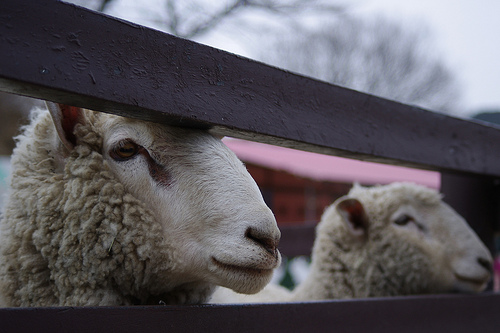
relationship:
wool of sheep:
[0, 105, 210, 309] [0, 98, 284, 307]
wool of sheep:
[287, 174, 442, 298] [293, 181, 494, 303]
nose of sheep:
[244, 218, 286, 253] [0, 98, 284, 307]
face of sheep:
[94, 109, 281, 292] [0, 98, 284, 307]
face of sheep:
[389, 197, 494, 288] [303, 183, 495, 293]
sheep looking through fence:
[12, 49, 288, 331] [2, 0, 499, 332]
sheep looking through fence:
[293, 181, 494, 303] [2, 0, 499, 332]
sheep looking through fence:
[0, 98, 284, 307] [2, 0, 499, 332]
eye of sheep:
[101, 128, 149, 164] [0, 98, 284, 307]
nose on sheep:
[244, 209, 286, 253] [0, 98, 284, 307]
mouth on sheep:
[208, 250, 283, 285] [0, 98, 284, 307]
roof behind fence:
[210, 120, 460, 205] [2, 0, 499, 332]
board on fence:
[4, 292, 495, 330] [2, 0, 499, 332]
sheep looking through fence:
[0, 98, 284, 307] [176, 42, 453, 162]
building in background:
[233, 141, 443, 197] [0, 8, 497, 213]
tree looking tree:
[226, 2, 464, 114] [68, 1, 347, 88]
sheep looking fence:
[325, 159, 487, 305] [41, 19, 487, 318]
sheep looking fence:
[0, 98, 284, 307] [41, 19, 487, 318]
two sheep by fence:
[2, 77, 496, 296] [2, 0, 499, 332]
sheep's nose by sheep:
[472, 253, 497, 277] [8, 83, 291, 317]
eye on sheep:
[101, 125, 150, 171] [13, 105, 287, 307]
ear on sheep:
[40, 85, 100, 160] [13, 105, 287, 307]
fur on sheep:
[10, 99, 216, 313] [0, 98, 284, 307]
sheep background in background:
[302, 189, 490, 294] [107, 1, 498, 114]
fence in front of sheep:
[2, 0, 499, 332] [200, 179, 492, 305]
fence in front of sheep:
[2, 0, 499, 332] [0, 98, 284, 307]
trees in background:
[202, 5, 404, 62] [107, 1, 498, 114]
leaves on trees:
[325, 26, 443, 88] [72, 2, 350, 66]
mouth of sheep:
[208, 250, 277, 285] [0, 98, 284, 307]